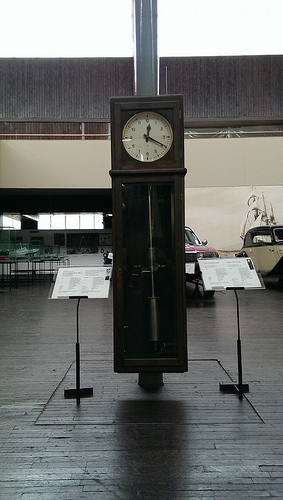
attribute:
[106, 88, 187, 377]
clock — dark, wooden, ahead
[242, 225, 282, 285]
car — displayed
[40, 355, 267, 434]
square — cut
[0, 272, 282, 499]
floor — dark, wooden.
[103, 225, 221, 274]
car — red